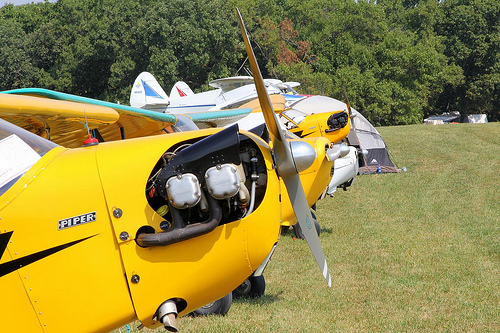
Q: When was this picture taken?
A: The day time.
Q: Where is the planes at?
A: Field.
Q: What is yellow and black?
A: The plane.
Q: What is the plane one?
A: Short cut grass.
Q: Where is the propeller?
A: On the front of the plane.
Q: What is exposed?
A: The engine.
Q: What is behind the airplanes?
A: The tall trees.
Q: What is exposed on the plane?
A: Engine.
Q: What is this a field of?
A: Brown and green grass.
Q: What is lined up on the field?
A: Airplanes.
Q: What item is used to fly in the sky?
A: A airplane.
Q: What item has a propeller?
A: A plane.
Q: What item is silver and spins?
A: A propeller.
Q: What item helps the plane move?
A: A propeller.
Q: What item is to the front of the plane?
A: A propeller.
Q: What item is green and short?
A: Grass.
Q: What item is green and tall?
A: Trees.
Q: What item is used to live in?
A: A house.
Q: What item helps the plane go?
A: A propeller.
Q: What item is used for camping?
A: A tent.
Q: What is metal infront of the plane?
A: A propeller.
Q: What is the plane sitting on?
A: Grass.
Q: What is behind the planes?
A: A tent.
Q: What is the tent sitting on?
A: Grass.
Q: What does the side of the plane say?
A: Piper.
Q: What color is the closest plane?
A: Yellow.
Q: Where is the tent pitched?
A: In a field.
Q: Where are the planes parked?
A: In a field.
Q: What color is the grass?
A: Green.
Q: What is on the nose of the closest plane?
A: A propeller.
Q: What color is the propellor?
A: Silver.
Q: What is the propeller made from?
A: Metal.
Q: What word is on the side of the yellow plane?
A: Piper.